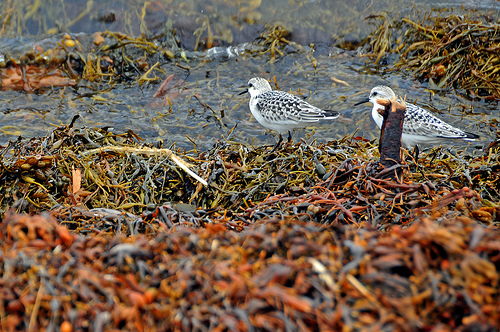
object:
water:
[0, 0, 500, 158]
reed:
[193, 95, 206, 108]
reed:
[214, 70, 220, 89]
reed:
[152, 73, 174, 98]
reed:
[137, 61, 161, 85]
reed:
[327, 73, 351, 86]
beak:
[237, 83, 248, 89]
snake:
[0, 22, 413, 69]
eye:
[248, 82, 252, 87]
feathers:
[462, 132, 465, 136]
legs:
[264, 132, 284, 163]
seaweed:
[0, 122, 500, 210]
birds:
[236, 75, 341, 160]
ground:
[0, 143, 500, 332]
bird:
[352, 84, 482, 156]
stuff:
[205, 151, 319, 221]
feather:
[456, 128, 485, 143]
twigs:
[138, 190, 140, 193]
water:
[43, 84, 250, 149]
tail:
[314, 108, 343, 122]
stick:
[374, 97, 407, 193]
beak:
[353, 97, 371, 107]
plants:
[365, 282, 378, 314]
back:
[254, 89, 324, 113]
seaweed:
[144, 207, 500, 332]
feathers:
[469, 135, 475, 136]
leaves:
[259, 275, 262, 286]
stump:
[0, 61, 82, 93]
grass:
[0, 0, 500, 332]